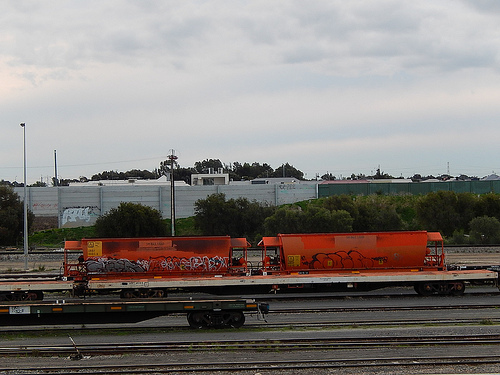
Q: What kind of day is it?
A: Cloudy.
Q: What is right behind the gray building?
A: Trees.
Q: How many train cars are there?
A: 2.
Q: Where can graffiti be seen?
A: Train.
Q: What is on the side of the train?
A: Graffiti.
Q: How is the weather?
A: Cloudy.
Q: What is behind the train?
A: Building.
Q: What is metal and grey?
A: Tracks.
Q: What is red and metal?
A: Containers.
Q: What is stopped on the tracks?
A: Train.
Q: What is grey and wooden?
A: Wall.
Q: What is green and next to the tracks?
A: Trees.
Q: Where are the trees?
A: Beside the train.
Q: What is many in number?
A: Train tracks.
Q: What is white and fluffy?
A: Clouds.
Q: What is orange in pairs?
A: Train cars.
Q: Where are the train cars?
A: Rail yard.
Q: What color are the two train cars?
A: Orange.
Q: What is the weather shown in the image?
A: Partly cloudy.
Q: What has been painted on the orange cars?
A: Graffiti.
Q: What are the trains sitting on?
A: Train tracks.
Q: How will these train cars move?
A: Locomotive.